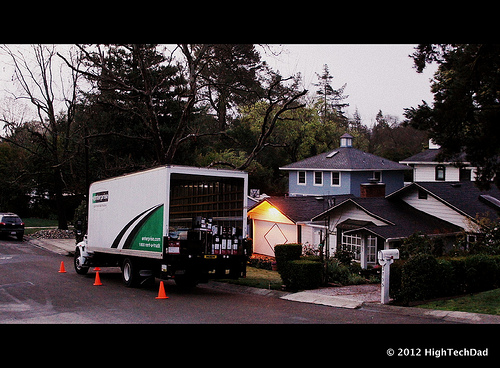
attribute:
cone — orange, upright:
[56, 258, 68, 276]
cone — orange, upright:
[89, 269, 105, 288]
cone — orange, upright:
[91, 263, 102, 273]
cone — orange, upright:
[150, 278, 173, 303]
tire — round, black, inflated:
[67, 249, 90, 277]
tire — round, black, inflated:
[117, 253, 143, 288]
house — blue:
[276, 130, 413, 199]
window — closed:
[371, 170, 386, 184]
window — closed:
[328, 173, 345, 187]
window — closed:
[312, 168, 326, 188]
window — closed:
[297, 168, 307, 188]